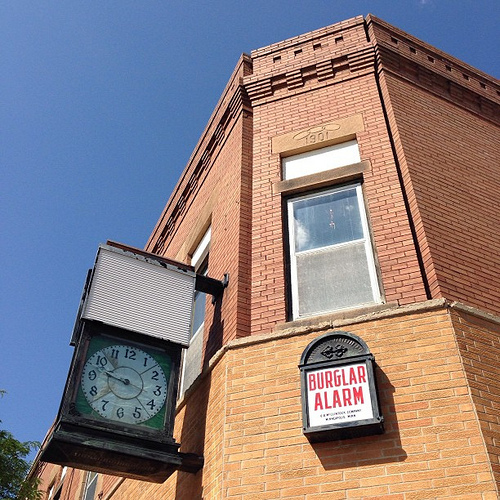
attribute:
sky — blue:
[43, 62, 200, 159]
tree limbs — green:
[2, 426, 49, 497]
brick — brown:
[340, 461, 389, 478]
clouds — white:
[59, 140, 152, 207]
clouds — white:
[74, 28, 136, 78]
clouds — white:
[407, 0, 450, 17]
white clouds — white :
[400, 0, 461, 21]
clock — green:
[75, 317, 169, 438]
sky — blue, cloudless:
[0, 0, 498, 497]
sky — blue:
[11, 17, 162, 212]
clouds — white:
[50, 34, 126, 82]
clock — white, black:
[53, 315, 191, 460]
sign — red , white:
[299, 355, 386, 437]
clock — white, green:
[83, 342, 168, 427]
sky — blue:
[432, 7, 485, 29]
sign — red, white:
[302, 361, 381, 423]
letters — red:
[309, 364, 367, 408]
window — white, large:
[284, 194, 381, 321]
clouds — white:
[2, 128, 82, 249]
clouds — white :
[20, 90, 123, 165]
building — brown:
[8, 16, 494, 497]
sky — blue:
[42, 15, 212, 75]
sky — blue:
[34, 27, 154, 160]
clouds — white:
[30, 37, 151, 187]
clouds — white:
[10, 127, 80, 282]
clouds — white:
[21, 129, 117, 223]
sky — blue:
[11, 89, 182, 183]